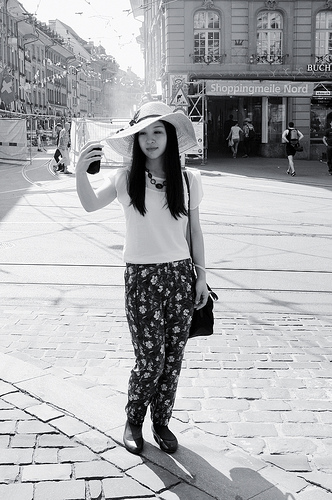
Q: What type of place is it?
A: It is a street.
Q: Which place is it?
A: It is a street.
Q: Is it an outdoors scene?
A: Yes, it is outdoors.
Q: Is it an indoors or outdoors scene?
A: It is outdoors.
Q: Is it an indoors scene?
A: No, it is outdoors.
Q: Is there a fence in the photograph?
A: No, there are no fences.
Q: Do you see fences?
A: No, there are no fences.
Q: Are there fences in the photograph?
A: No, there are no fences.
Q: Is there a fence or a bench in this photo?
A: No, there are no fences or benches.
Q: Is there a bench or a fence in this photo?
A: No, there are no fences or benches.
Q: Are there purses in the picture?
A: Yes, there is a purse.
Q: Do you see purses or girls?
A: Yes, there is a purse.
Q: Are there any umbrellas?
A: No, there are no umbrellas.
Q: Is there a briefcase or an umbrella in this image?
A: No, there are no umbrellas or briefcases.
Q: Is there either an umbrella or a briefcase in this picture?
A: No, there are no umbrellas or briefcases.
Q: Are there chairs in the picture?
A: No, there are no chairs.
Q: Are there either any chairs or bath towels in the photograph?
A: No, there are no chairs or bath towels.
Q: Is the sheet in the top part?
A: Yes, the sheet is in the top of the image.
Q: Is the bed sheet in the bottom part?
A: No, the bed sheet is in the top of the image.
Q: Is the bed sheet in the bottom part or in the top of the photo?
A: The bed sheet is in the top of the image.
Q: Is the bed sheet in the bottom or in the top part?
A: The bed sheet is in the top of the image.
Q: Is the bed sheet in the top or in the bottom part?
A: The bed sheet is in the top of the image.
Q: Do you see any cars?
A: No, there are no cars.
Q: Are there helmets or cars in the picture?
A: No, there are no cars or helmets.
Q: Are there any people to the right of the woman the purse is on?
A: Yes, there is a person to the right of the woman.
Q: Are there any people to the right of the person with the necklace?
A: Yes, there is a person to the right of the woman.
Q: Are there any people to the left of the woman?
A: No, the person is to the right of the woman.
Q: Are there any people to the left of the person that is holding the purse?
A: No, the person is to the right of the woman.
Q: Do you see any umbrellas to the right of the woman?
A: No, there is a person to the right of the woman.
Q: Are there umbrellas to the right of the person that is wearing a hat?
A: No, there is a person to the right of the woman.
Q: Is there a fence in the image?
A: No, there are no fences.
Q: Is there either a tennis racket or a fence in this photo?
A: No, there are no fences or rackets.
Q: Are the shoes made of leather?
A: Yes, the shoes are made of leather.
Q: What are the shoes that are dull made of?
A: The shoes are made of leather.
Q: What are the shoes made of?
A: The shoes are made of leather.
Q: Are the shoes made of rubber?
A: No, the shoes are made of leather.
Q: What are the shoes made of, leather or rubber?
A: The shoes are made of leather.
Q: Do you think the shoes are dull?
A: Yes, the shoes are dull.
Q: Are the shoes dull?
A: Yes, the shoes are dull.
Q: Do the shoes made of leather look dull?
A: Yes, the shoes are dull.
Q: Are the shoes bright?
A: No, the shoes are dull.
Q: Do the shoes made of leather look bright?
A: No, the shoes are dull.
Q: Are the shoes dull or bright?
A: The shoes are dull.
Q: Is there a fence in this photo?
A: No, there are no fences.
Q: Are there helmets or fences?
A: No, there are no fences or helmets.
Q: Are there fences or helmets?
A: No, there are no fences or helmets.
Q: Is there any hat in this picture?
A: Yes, there is a hat.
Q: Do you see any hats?
A: Yes, there is a hat.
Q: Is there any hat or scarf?
A: Yes, there is a hat.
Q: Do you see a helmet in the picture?
A: No, there are no helmets.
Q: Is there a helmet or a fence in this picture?
A: No, there are no helmets or fences.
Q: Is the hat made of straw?
A: Yes, the hat is made of straw.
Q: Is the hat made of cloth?
A: No, the hat is made of straw.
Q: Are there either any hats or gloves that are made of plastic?
A: No, there is a hat but it is made of straw.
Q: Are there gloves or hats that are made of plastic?
A: No, there is a hat but it is made of straw.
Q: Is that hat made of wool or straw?
A: The hat is made of straw.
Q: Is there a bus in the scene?
A: No, there are no buses.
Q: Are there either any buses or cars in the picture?
A: No, there are no buses or cars.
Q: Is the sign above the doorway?
A: Yes, the sign is above the doorway.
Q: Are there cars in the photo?
A: No, there are no cars.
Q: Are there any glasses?
A: No, there are no glasses.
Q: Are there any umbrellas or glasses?
A: No, there are no glasses or umbrellas.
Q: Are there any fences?
A: No, there are no fences.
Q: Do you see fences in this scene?
A: No, there are no fences.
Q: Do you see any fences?
A: No, there are no fences.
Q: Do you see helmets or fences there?
A: No, there are no fences or helmets.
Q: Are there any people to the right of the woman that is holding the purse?
A: Yes, there is a person to the right of the woman.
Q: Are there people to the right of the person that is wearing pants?
A: Yes, there is a person to the right of the woman.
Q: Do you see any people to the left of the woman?
A: No, the person is to the right of the woman.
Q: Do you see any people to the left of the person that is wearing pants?
A: No, the person is to the right of the woman.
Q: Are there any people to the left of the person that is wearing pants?
A: No, the person is to the right of the woman.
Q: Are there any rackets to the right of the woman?
A: No, there is a person to the right of the woman.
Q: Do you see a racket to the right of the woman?
A: No, there is a person to the right of the woman.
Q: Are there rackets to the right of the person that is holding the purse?
A: No, there is a person to the right of the woman.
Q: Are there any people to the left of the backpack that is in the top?
A: Yes, there is a person to the left of the backpack.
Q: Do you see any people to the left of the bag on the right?
A: Yes, there is a person to the left of the backpack.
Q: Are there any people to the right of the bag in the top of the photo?
A: No, the person is to the left of the backpack.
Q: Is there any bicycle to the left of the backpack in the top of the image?
A: No, there is a person to the left of the backpack.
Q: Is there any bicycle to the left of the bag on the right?
A: No, there is a person to the left of the backpack.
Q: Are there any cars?
A: No, there are no cars.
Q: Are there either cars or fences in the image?
A: No, there are no cars or fences.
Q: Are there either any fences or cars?
A: No, there are no cars or fences.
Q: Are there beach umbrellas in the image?
A: No, there are no beach umbrellas.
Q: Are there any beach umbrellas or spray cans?
A: No, there are no beach umbrellas or spray cans.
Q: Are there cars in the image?
A: No, there are no cars.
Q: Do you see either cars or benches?
A: No, there are no cars or benches.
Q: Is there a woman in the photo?
A: Yes, there is a woman.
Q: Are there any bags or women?
A: Yes, there is a woman.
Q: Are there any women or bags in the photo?
A: Yes, there is a woman.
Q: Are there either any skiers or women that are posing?
A: Yes, the woman is posing.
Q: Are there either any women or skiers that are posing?
A: Yes, the woman is posing.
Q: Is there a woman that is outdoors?
A: Yes, there is a woman that is outdoors.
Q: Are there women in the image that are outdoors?
A: Yes, there is a woman that is outdoors.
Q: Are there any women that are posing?
A: Yes, there is a woman that is posing.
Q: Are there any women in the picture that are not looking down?
A: Yes, there is a woman that is posing.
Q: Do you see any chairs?
A: No, there are no chairs.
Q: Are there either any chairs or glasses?
A: No, there are no chairs or glasses.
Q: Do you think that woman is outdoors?
A: Yes, the woman is outdoors.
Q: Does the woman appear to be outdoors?
A: Yes, the woman is outdoors.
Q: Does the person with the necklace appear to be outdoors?
A: Yes, the woman is outdoors.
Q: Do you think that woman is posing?
A: Yes, the woman is posing.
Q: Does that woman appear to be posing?
A: Yes, the woman is posing.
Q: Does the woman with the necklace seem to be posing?
A: Yes, the woman is posing.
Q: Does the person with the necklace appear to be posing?
A: Yes, the woman is posing.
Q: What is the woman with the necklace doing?
A: The woman is posing.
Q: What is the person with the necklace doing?
A: The woman is posing.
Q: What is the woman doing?
A: The woman is posing.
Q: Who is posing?
A: The woman is posing.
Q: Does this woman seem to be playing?
A: No, the woman is posing.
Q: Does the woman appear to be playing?
A: No, the woman is posing.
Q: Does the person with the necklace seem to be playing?
A: No, the woman is posing.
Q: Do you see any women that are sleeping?
A: No, there is a woman but she is posing.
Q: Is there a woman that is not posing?
A: No, there is a woman but she is posing.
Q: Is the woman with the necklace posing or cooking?
A: The woman is posing.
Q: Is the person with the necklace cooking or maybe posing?
A: The woman is posing.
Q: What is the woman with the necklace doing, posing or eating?
A: The woman is posing.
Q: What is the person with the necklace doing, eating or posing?
A: The woman is posing.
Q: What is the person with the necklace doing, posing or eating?
A: The woman is posing.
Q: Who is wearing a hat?
A: The woman is wearing a hat.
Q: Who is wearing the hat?
A: The woman is wearing a hat.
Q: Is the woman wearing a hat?
A: Yes, the woman is wearing a hat.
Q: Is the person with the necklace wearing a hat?
A: Yes, the woman is wearing a hat.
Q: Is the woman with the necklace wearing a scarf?
A: No, the woman is wearing a hat.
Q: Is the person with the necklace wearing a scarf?
A: No, the woman is wearing a hat.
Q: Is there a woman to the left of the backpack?
A: Yes, there is a woman to the left of the backpack.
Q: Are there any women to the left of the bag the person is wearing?
A: Yes, there is a woman to the left of the backpack.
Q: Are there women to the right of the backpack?
A: No, the woman is to the left of the backpack.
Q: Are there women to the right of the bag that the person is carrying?
A: No, the woman is to the left of the backpack.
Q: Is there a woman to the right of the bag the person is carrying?
A: No, the woman is to the left of the backpack.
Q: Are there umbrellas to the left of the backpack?
A: No, there is a woman to the left of the backpack.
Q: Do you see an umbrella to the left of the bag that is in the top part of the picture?
A: No, there is a woman to the left of the backpack.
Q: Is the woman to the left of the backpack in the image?
A: Yes, the woman is to the left of the backpack.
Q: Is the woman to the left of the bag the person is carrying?
A: Yes, the woman is to the left of the backpack.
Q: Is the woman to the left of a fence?
A: No, the woman is to the left of the backpack.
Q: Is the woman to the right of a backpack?
A: No, the woman is to the left of a backpack.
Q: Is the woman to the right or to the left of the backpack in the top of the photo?
A: The woman is to the left of the backpack.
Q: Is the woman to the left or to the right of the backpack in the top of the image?
A: The woman is to the left of the backpack.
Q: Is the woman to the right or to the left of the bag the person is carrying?
A: The woman is to the left of the backpack.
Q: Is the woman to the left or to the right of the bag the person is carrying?
A: The woman is to the left of the backpack.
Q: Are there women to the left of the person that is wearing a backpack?
A: Yes, there is a woman to the left of the person.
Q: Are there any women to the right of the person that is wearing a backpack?
A: No, the woman is to the left of the person.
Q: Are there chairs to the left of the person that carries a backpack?
A: No, there is a woman to the left of the person.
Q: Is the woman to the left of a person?
A: Yes, the woman is to the left of a person.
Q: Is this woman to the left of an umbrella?
A: No, the woman is to the left of a person.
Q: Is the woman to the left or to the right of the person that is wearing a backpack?
A: The woman is to the left of the person.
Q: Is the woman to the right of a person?
A: No, the woman is to the left of a person.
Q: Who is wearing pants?
A: The woman is wearing pants.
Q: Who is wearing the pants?
A: The woman is wearing pants.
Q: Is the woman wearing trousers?
A: Yes, the woman is wearing trousers.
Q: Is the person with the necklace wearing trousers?
A: Yes, the woman is wearing trousers.